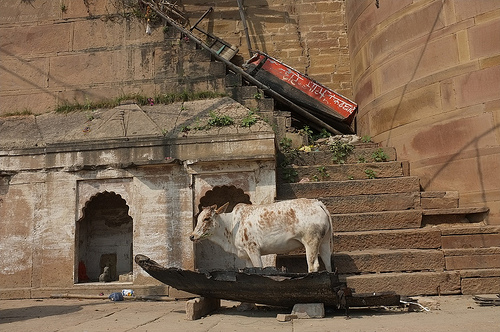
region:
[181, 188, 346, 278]
Cow near a flight of Stairs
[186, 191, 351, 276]
white cow on the stairs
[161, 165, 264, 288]
white cow on the stairs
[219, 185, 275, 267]
white cow on the stairs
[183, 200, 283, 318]
white cow on the stairs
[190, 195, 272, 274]
white cow on the stairs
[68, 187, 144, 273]
door way to a building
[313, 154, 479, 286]
brick steps attached to building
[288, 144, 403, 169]
grass growing by steps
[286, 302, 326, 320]
cement block beside dog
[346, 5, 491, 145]
brick building on sidewalk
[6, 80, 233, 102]
grass growing on building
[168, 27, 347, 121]
steps attached to the building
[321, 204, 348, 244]
tail of a dog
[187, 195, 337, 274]
cow standing near steps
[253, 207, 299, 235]
brown spots on cow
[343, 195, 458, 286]
concrete stairs are gray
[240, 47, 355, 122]
red sign laying on stairs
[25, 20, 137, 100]
large brown stone brick wall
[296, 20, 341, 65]
small brown brick wall with white motar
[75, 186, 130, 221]
carved stone top of entry way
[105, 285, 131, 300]
trash on ground near entrance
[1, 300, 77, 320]
shadow on ground near entrance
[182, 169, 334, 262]
cow in the photo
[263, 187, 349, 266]
back part of cow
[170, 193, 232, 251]
head of the animal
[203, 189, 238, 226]
ear of the animal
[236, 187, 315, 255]
body of the animal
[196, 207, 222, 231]
eye of the animal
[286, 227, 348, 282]
back legs of the animal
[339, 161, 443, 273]
stairs in the photo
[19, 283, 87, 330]
shadow on the ground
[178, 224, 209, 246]
nose of the animal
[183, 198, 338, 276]
white and brown cow standing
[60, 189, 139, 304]
small archway in door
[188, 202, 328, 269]
brown and white cow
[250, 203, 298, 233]
brown spots on cow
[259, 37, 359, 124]
red sign tilted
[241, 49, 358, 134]
fallen down red sign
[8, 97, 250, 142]
concrete roof of building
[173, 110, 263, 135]
green plants on top of roof